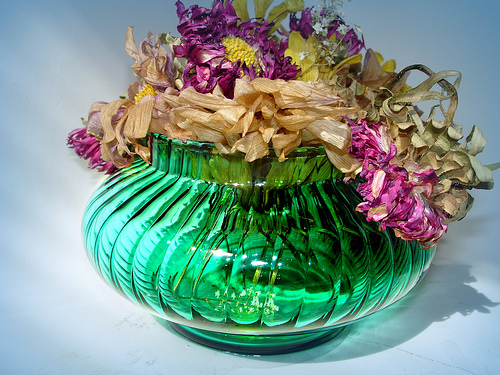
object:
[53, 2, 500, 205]
flowers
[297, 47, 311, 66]
white stigma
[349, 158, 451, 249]
flower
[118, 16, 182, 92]
flower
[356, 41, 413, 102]
flower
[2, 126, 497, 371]
surface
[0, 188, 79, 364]
table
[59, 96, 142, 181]
flower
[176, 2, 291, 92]
flower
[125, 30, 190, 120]
flower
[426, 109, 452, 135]
ground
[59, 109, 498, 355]
pot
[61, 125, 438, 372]
vase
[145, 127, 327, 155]
rim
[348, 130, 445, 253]
purple flower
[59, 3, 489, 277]
decoration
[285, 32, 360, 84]
flower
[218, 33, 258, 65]
flower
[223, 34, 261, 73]
yellow bits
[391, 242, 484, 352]
shadow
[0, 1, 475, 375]
floor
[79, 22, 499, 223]
leaves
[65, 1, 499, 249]
flowers